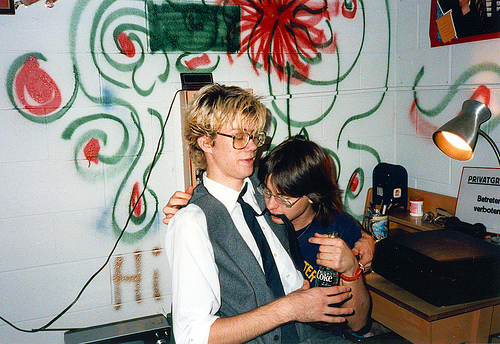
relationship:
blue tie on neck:
[235, 180, 303, 343] [198, 167, 265, 203]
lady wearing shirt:
[163, 134, 383, 344] [288, 213, 361, 285]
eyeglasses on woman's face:
[255, 183, 305, 213] [262, 180, 300, 227]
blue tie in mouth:
[235, 180, 303, 343] [265, 209, 286, 222]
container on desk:
[371, 162, 408, 216] [375, 218, 458, 306]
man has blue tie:
[157, 82, 357, 341] [237, 189, 304, 342]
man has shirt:
[157, 82, 376, 344] [291, 211, 368, 328]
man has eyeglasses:
[272, 124, 332, 216] [255, 187, 302, 208]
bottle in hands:
[311, 231, 347, 306] [293, 230, 354, 324]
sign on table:
[448, 165, 493, 240] [300, 187, 497, 341]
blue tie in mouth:
[235, 180, 303, 343] [260, 199, 305, 227]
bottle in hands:
[311, 231, 341, 331] [293, 230, 354, 324]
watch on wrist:
[338, 265, 363, 281] [344, 259, 365, 280]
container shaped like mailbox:
[370, 157, 422, 207] [370, 152, 417, 213]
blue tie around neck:
[235, 180, 303, 343] [202, 163, 254, 199]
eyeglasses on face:
[210, 124, 268, 152] [193, 96, 264, 183]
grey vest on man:
[184, 179, 307, 342] [157, 82, 357, 341]